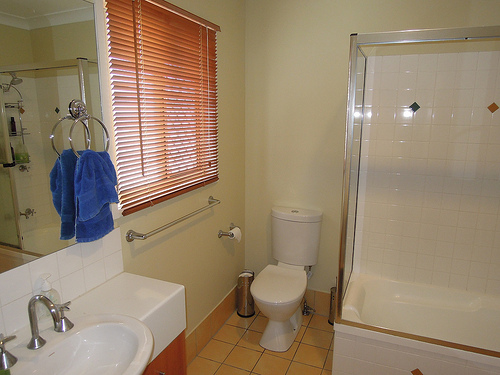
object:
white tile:
[431, 108, 452, 125]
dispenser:
[53, 300, 75, 332]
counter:
[0, 271, 185, 374]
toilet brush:
[301, 300, 311, 316]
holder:
[217, 221, 236, 239]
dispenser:
[217, 228, 234, 240]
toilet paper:
[228, 227, 243, 242]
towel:
[73, 150, 120, 244]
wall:
[243, 0, 499, 297]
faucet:
[27, 293, 74, 350]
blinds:
[104, 0, 219, 216]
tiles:
[285, 360, 323, 375]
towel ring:
[69, 115, 111, 158]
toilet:
[247, 206, 323, 354]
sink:
[11, 314, 155, 375]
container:
[236, 269, 253, 318]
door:
[338, 25, 500, 356]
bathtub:
[340, 275, 499, 351]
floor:
[183, 303, 335, 373]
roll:
[229, 225, 243, 240]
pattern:
[221, 343, 263, 371]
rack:
[68, 100, 87, 120]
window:
[107, 0, 216, 207]